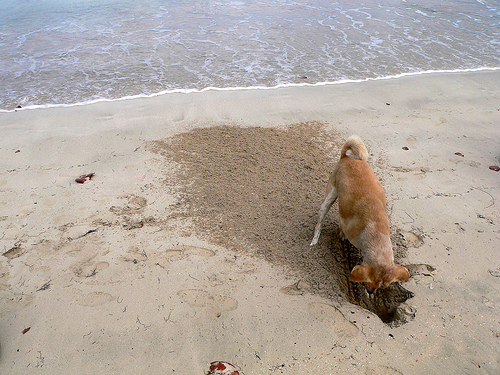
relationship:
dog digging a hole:
[316, 138, 415, 290] [358, 294, 414, 331]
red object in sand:
[205, 358, 243, 374] [12, 74, 497, 373]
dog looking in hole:
[316, 138, 415, 290] [358, 294, 414, 331]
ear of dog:
[349, 260, 370, 289] [316, 138, 415, 290]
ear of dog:
[392, 265, 412, 284] [316, 138, 415, 290]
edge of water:
[81, 67, 499, 107] [1, 3, 499, 107]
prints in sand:
[66, 247, 244, 323] [12, 74, 497, 373]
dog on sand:
[316, 138, 415, 290] [12, 74, 497, 373]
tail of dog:
[340, 134, 370, 162] [316, 138, 415, 290]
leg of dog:
[306, 184, 339, 250] [316, 138, 415, 290]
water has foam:
[1, 3, 499, 107] [194, 83, 221, 94]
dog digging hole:
[316, 138, 415, 290] [358, 294, 414, 331]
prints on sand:
[66, 247, 244, 323] [12, 74, 497, 373]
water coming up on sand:
[1, 3, 499, 107] [12, 74, 497, 373]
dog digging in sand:
[316, 138, 415, 290] [12, 74, 497, 373]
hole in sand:
[358, 294, 414, 331] [12, 74, 497, 373]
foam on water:
[194, 83, 221, 94] [1, 3, 499, 107]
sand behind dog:
[207, 128, 315, 231] [316, 138, 415, 290]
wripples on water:
[64, 17, 213, 57] [1, 3, 499, 107]